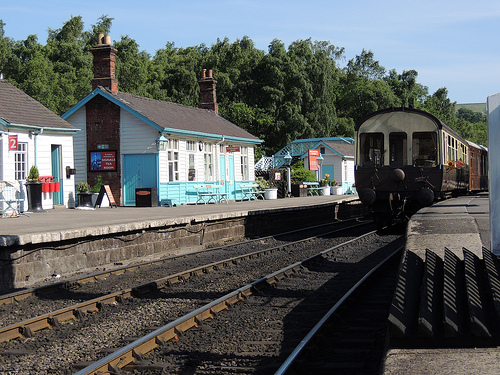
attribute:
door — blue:
[45, 139, 76, 206]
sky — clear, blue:
[361, 24, 485, 79]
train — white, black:
[361, 108, 458, 228]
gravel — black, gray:
[75, 223, 394, 373]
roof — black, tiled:
[50, 80, 269, 143]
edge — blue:
[157, 125, 269, 149]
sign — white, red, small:
[95, 184, 117, 206]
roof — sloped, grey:
[114, 86, 255, 138]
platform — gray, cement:
[2, 192, 364, 297]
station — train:
[101, 91, 498, 333]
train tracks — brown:
[27, 214, 367, 374]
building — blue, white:
[2, 65, 82, 213]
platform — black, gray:
[388, 185, 496, 374]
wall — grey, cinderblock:
[7, 202, 364, 288]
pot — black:
[17, 170, 54, 216]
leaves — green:
[178, 55, 337, 106]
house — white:
[3, 80, 82, 212]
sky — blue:
[2, 0, 499, 107]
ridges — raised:
[391, 240, 499, 342]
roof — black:
[0, 78, 70, 129]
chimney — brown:
[85, 34, 121, 94]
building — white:
[61, 84, 263, 208]